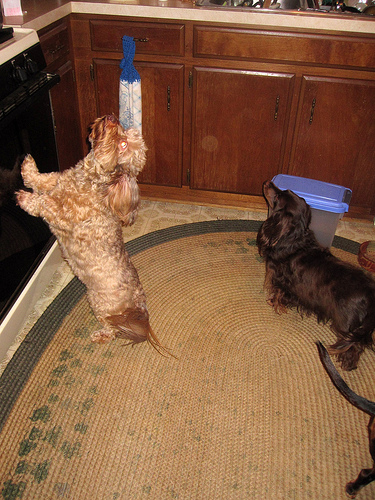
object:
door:
[188, 67, 294, 196]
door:
[92, 60, 185, 188]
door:
[287, 75, 375, 209]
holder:
[120, 35, 149, 46]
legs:
[90, 319, 117, 346]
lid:
[268, 172, 353, 215]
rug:
[0, 218, 374, 497]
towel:
[118, 34, 141, 138]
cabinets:
[69, 15, 374, 223]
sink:
[206, 0, 302, 11]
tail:
[313, 338, 374, 419]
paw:
[20, 152, 37, 184]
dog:
[13, 111, 179, 359]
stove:
[0, 24, 66, 326]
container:
[269, 173, 352, 250]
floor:
[0, 193, 374, 498]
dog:
[255, 180, 373, 372]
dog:
[311, 338, 374, 498]